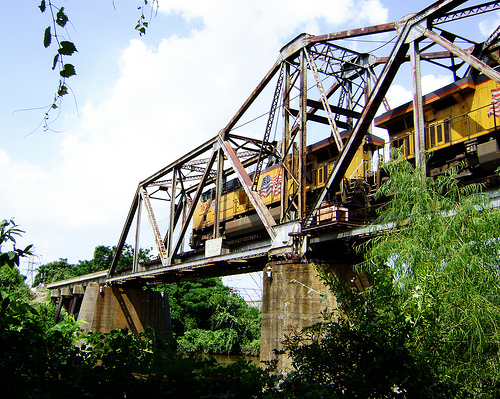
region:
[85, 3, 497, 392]
train resting on bridge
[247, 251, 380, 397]
base supporting the bridge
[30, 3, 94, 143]
hanging branch of tree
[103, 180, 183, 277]
metal infrastructure of bridge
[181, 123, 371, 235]
a car on the train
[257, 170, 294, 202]
picture of American flag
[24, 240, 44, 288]
pole for electrical signals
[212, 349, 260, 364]
water beneath the bridge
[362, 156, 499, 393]
tree resting close to bridge and train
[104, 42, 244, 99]
part of cloud in sky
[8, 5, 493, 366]
This is a bridge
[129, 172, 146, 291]
This is a metal bar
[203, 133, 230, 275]
This is a metal bar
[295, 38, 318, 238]
This is a metal bar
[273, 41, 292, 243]
This is a metal bar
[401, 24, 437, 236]
This is a metal bar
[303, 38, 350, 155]
This is a metal bar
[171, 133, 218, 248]
This is a metal bar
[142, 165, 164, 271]
This is a metal bar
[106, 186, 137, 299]
This is a metal bar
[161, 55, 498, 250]
yellow train on an open bridge over trees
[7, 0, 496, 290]
open bridge with train tracks and a yellow train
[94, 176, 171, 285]
triangle arch on an open bridge with train tracks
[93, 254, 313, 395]
underneath of an open bridge with train tracks on it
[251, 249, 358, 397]
pillar holding up an open bridge with a train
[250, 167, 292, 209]
american flag on a yellow train on an open bridge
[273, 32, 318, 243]
metal support on an open bridge with a train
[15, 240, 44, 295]
eletric tower near an open bridge with a train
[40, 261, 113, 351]
open bridge with train tracks on it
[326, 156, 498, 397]
tree near an open bridge with a yellow train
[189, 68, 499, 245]
A large yellow train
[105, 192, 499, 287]
A railroad bridge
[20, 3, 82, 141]
An overhanging branch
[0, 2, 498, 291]
A clear blue sky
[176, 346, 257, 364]
A small body of water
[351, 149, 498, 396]
A large full bush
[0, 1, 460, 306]
some clouds in the sky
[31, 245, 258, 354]
A small wooded area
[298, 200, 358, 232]
A metal platform on the bridge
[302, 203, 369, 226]
Some metal guard railing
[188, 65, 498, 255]
yellow train crossing a bridge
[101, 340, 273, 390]
brown water under a bridge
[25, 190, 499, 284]
track on a span across water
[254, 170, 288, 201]
american flag on the side of a train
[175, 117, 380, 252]
engin on a train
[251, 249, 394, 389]
stone column in the middle of a bridge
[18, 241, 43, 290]
metal tower standing in the distance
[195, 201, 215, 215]
number on the train engine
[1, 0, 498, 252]
light blue clear sky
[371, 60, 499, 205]
yellow colored train car